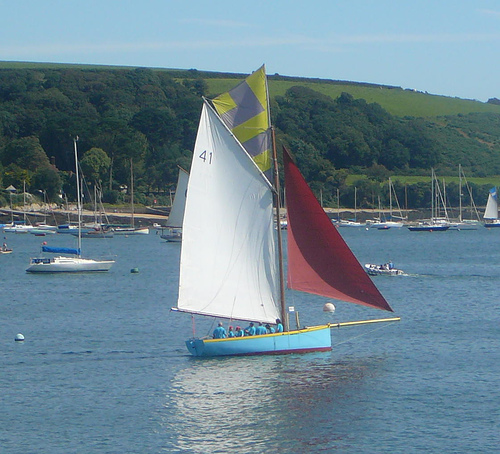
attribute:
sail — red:
[175, 83, 406, 323]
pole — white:
[72, 140, 82, 258]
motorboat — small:
[364, 260, 406, 275]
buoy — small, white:
[283, 282, 333, 317]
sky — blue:
[2, 3, 498, 103]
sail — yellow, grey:
[151, 64, 415, 389]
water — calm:
[387, 307, 472, 417]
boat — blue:
[188, 330, 342, 355]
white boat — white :
[25, 256, 115, 272]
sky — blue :
[375, 7, 431, 49]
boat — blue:
[168, 300, 373, 365]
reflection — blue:
[167, 348, 384, 452]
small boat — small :
[185, 325, 331, 357]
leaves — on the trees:
[137, 112, 174, 135]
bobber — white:
[14, 328, 28, 341]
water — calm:
[45, 319, 139, 414]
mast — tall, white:
[171, 98, 281, 321]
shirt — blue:
[214, 329, 224, 336]